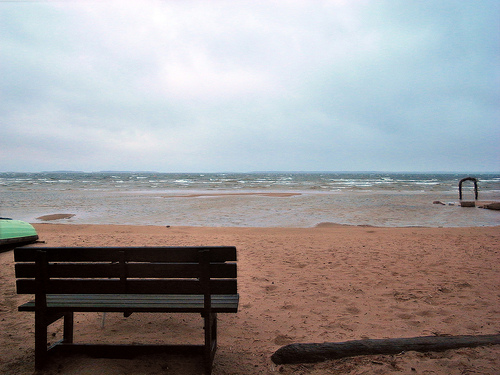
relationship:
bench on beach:
[9, 238, 241, 368] [3, 220, 500, 375]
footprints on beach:
[229, 238, 496, 372] [3, 220, 500, 375]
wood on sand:
[268, 333, 498, 367] [0, 223, 499, 373]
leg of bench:
[200, 308, 221, 367] [9, 238, 241, 368]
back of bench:
[10, 245, 241, 315] [9, 238, 241, 368]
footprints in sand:
[229, 238, 496, 372] [0, 223, 499, 373]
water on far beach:
[0, 181, 500, 229] [0, 184, 499, 230]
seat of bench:
[15, 291, 239, 316] [9, 238, 241, 368]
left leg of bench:
[30, 309, 72, 372] [9, 238, 241, 368]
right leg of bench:
[197, 309, 225, 369] [9, 238, 241, 368]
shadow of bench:
[29, 330, 217, 375] [9, 238, 241, 368]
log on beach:
[268, 331, 499, 375] [3, 220, 500, 375]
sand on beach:
[0, 223, 499, 373] [3, 220, 500, 375]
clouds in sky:
[0, 0, 499, 176] [1, 0, 499, 175]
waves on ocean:
[4, 171, 499, 189] [3, 166, 500, 194]